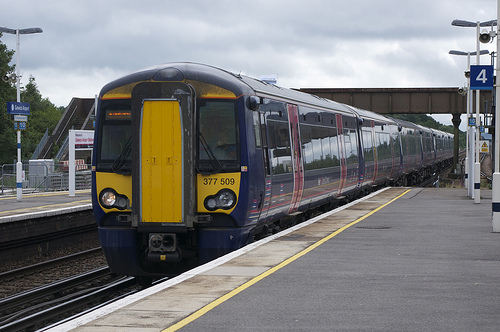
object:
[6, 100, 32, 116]
sign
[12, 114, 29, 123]
sign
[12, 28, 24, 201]
pole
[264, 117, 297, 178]
window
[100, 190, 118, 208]
headlights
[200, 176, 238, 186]
377 509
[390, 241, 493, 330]
gray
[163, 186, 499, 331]
cement area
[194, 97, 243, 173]
windshield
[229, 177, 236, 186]
number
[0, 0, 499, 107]
cloud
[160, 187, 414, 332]
line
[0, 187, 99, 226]
platform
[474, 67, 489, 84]
number 4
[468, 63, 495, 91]
sign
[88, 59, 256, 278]
front end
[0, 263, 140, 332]
tracks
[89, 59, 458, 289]
passenger train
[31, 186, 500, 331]
train station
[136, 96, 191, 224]
door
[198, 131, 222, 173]
windshield wiper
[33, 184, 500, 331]
crosswalk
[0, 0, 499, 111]
sky